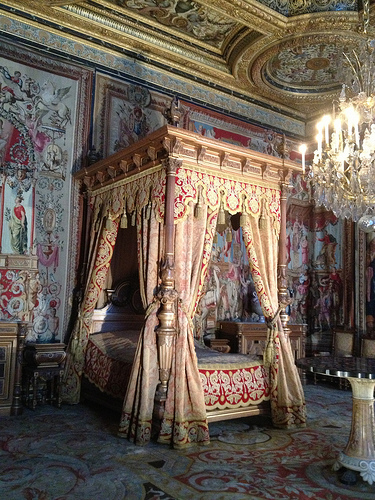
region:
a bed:
[102, 332, 137, 362]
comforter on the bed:
[196, 338, 239, 372]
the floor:
[197, 453, 287, 491]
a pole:
[153, 174, 186, 265]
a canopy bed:
[89, 173, 277, 211]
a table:
[315, 353, 374, 381]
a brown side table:
[30, 338, 68, 371]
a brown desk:
[231, 318, 255, 334]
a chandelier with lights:
[313, 143, 373, 190]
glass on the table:
[327, 355, 367, 376]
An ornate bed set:
[52, 113, 319, 438]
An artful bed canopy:
[65, 127, 309, 431]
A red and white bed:
[84, 327, 266, 404]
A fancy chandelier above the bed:
[295, 86, 373, 229]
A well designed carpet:
[31, 419, 349, 498]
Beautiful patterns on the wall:
[0, 76, 78, 326]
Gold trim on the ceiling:
[21, 0, 353, 66]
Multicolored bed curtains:
[130, 188, 213, 446]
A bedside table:
[28, 336, 77, 421]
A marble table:
[306, 347, 374, 455]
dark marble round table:
[290, 350, 372, 498]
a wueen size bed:
[82, 327, 283, 415]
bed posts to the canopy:
[155, 138, 183, 430]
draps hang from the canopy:
[181, 174, 294, 442]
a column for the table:
[332, 381, 373, 476]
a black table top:
[296, 345, 373, 381]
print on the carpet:
[164, 444, 293, 498]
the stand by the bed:
[25, 337, 67, 406]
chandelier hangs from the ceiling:
[296, 2, 374, 243]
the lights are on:
[299, 111, 374, 176]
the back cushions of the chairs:
[333, 331, 373, 354]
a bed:
[103, 204, 214, 498]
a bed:
[140, 260, 230, 490]